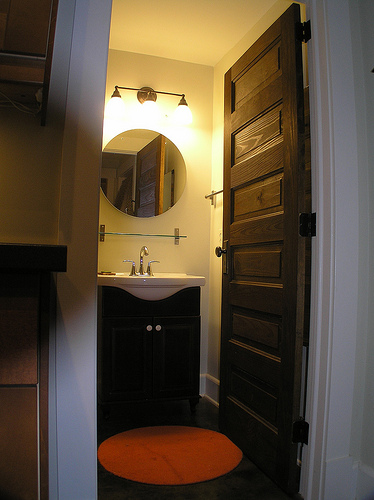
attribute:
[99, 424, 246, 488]
rug — orange, round, small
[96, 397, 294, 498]
floor — black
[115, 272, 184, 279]
sink — white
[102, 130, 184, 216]
mirror — circular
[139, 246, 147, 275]
faucet — silver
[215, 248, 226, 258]
doorknob — metallic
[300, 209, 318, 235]
door hinge — black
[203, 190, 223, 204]
towel rack — silver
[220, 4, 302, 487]
door — open, wide open, open in the room, not closed, opened to the room, wooden